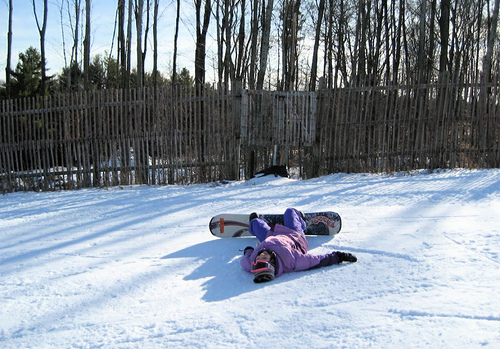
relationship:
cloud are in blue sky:
[0, 0, 496, 87] [1, 1, 499, 95]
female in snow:
[240, 208, 358, 284] [36, 170, 498, 343]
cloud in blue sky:
[0, 0, 496, 87] [1, 1, 499, 95]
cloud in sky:
[0, 0, 496, 87] [0, 0, 498, 102]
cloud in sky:
[143, 38, 220, 83] [0, 0, 498, 102]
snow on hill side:
[63, 222, 115, 299] [0, 167, 495, 346]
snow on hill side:
[36, 170, 498, 343] [0, 167, 495, 346]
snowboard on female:
[207, 211, 342, 236] [240, 208, 358, 284]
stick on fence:
[0, 76, 500, 193] [0, 84, 496, 181]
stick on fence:
[0, 76, 500, 193] [23, 82, 486, 171]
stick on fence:
[0, 76, 500, 193] [2, 78, 497, 194]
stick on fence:
[54, 93, 64, 189] [2, 78, 497, 194]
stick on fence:
[0, 76, 500, 193] [3, 62, 498, 194]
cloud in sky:
[0, 0, 496, 87] [37, 12, 499, 127]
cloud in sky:
[0, 0, 496, 87] [159, 1, 340, 68]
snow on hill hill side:
[0, 171, 500, 349] [0, 167, 495, 346]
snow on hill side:
[36, 170, 498, 343] [29, 185, 112, 285]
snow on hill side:
[0, 171, 500, 349] [0, 167, 495, 346]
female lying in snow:
[194, 171, 344, 298] [51, 217, 174, 349]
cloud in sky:
[0, 0, 496, 87] [9, 11, 444, 93]